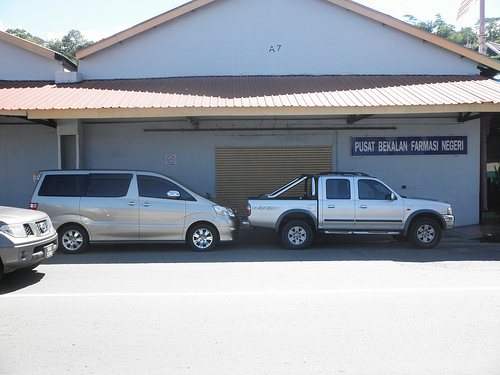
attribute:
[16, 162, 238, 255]
car — silver, parked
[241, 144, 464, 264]
truck — parked, silver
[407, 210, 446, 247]
wheel — black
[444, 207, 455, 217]
light — white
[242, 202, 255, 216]
light — red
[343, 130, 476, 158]
sign — black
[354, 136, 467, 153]
writing — white